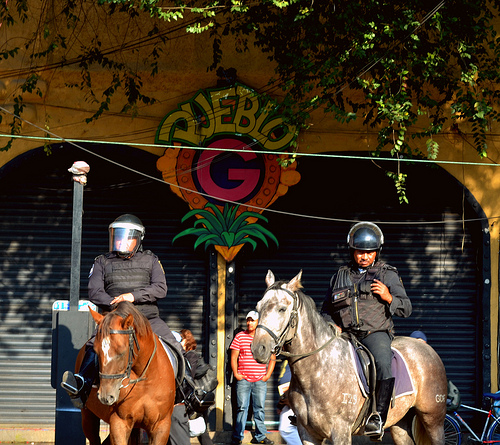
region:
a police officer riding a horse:
[61, 213, 213, 443]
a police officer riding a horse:
[246, 216, 453, 443]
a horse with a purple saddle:
[247, 269, 454, 444]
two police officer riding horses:
[60, 210, 451, 443]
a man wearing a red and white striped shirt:
[227, 308, 278, 443]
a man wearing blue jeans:
[228, 308, 275, 444]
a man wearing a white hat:
[225, 308, 276, 443]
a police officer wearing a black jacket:
[324, 216, 416, 444]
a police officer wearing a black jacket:
[59, 213, 213, 419]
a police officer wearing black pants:
[320, 222, 415, 440]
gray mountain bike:
[410, 388, 498, 443]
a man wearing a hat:
[231, 311, 277, 442]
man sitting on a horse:
[61, 211, 214, 411]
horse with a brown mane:
[77, 303, 177, 443]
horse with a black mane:
[250, 267, 448, 442]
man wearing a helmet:
[281, 220, 413, 440]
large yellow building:
[0, 0, 498, 441]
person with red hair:
[174, 329, 197, 351]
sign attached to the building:
[153, 86, 298, 262]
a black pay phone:
[51, 160, 101, 442]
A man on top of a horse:
[334, 218, 414, 443]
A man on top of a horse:
[61, 216, 201, 401]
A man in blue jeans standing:
[231, 311, 281, 443]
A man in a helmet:
[331, 226, 408, 443]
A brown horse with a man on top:
[74, 306, 180, 443]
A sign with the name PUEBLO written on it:
[149, 84, 301, 156]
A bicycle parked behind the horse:
[442, 383, 497, 443]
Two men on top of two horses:
[55, 212, 452, 443]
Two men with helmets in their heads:
[52, 209, 449, 442]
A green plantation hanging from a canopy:
[166, 202, 283, 264]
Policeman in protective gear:
[317, 218, 412, 443]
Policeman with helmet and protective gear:
[58, 210, 218, 422]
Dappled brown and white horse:
[247, 266, 451, 443]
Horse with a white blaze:
[70, 297, 180, 442]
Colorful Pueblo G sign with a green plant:
[150, 80, 303, 266]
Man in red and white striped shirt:
[225, 309, 279, 444]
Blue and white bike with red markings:
[404, 380, 499, 443]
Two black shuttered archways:
[0, 135, 496, 436]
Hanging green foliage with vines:
[0, 2, 497, 205]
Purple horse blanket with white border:
[340, 332, 417, 406]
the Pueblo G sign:
[152, 78, 302, 260]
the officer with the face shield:
[85, 210, 176, 327]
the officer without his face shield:
[323, 213, 403, 436]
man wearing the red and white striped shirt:
[223, 300, 283, 442]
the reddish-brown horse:
[71, 296, 171, 443]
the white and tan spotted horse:
[251, 267, 456, 443]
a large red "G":
[190, 129, 269, 212]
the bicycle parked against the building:
[430, 367, 497, 444]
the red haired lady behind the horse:
[172, 326, 216, 441]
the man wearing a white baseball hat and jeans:
[225, 303, 275, 444]